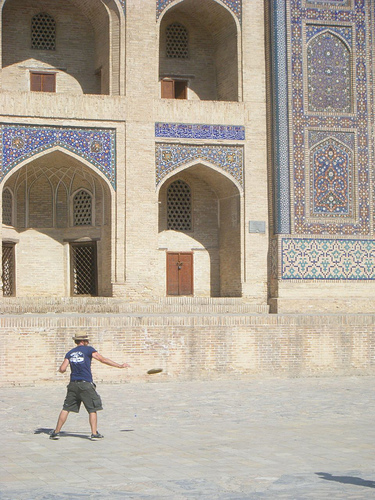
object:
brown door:
[163, 251, 194, 297]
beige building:
[0, 0, 375, 387]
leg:
[53, 388, 82, 431]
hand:
[120, 362, 134, 375]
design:
[293, 271, 299, 279]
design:
[286, 246, 298, 261]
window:
[164, 174, 196, 231]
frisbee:
[147, 367, 161, 380]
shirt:
[64, 345, 95, 381]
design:
[362, 206, 367, 210]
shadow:
[311, 467, 375, 493]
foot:
[53, 429, 62, 436]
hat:
[72, 330, 90, 343]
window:
[68, 185, 95, 227]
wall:
[0, 309, 375, 388]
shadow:
[119, 427, 136, 435]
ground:
[0, 373, 375, 498]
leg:
[80, 385, 102, 434]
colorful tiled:
[279, 237, 375, 284]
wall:
[277, 0, 375, 295]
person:
[49, 327, 133, 443]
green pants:
[61, 380, 104, 415]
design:
[296, 256, 309, 271]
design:
[328, 151, 337, 159]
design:
[226, 151, 236, 169]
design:
[91, 142, 103, 153]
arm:
[88, 346, 120, 372]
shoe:
[92, 430, 106, 442]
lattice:
[72, 241, 100, 297]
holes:
[174, 207, 180, 216]